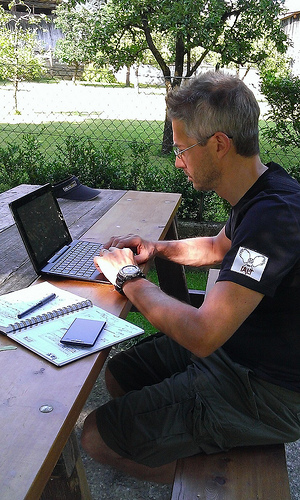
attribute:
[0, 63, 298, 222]
fence — chain link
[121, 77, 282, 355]
person — face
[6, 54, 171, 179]
fence — chain link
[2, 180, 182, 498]
bench — wooden, picnic bench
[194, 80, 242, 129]
hair — graying, mans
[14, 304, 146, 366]
cover — black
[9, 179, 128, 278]
laptop — nice, wide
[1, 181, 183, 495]
picnic table — wooden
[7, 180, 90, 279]
laptop — open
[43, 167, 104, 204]
visor — blue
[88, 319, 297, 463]
shorts — gray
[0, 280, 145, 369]
notebook — spiral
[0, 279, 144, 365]
book — thread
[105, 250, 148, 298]
watch — black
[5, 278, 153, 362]
file — mobile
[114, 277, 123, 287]
metal — dark tinted 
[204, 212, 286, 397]
shirt — black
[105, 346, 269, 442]
shorts — black